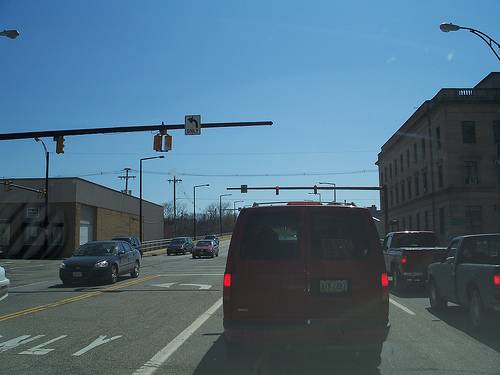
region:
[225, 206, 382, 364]
yellow bus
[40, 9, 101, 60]
white clouds in blue sky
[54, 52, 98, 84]
white clouds in blue sky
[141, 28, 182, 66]
white clouds in blue sky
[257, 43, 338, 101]
white clouds in blue sky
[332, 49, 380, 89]
white clouds in blue sky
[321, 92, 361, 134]
white clouds in blue sky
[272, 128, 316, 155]
white clouds in blue sky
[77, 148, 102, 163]
white clouds in blue sky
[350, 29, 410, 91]
white clouds in blue sky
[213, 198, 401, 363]
Rear of red truck stopping in traffic.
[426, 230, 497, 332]
White pick up truck stopping in traffic.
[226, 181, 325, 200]
Traffic lights hanging over street.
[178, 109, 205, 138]
Directional traffic sign next to traffic lights.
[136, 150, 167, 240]
Lamp post standing on sidewalk.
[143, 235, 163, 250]
Railing along sidwalk next to street.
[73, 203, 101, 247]
Wide white door on side of building.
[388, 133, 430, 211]
Windows along side of building.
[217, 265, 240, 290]
Break light on rear of red truck.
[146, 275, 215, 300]
White traffic directional arrow painted on street.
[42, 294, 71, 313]
a yellow line in the street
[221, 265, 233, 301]
a red light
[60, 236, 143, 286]
a car in the street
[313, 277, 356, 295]
a license plate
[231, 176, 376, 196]
a traffic signal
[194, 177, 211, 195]
a street light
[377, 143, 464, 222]
a building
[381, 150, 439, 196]
windows on the building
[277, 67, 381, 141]
the sky is blue and clear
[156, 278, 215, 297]
a white arrow on the street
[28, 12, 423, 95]
Sky is blue color.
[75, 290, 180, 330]
Road is grey color.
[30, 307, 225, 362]
White lines in road.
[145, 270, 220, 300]
Arrow is white color.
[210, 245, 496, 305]
Red light is on in the car rear.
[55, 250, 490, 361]
Shadow falls on the road.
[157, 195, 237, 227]
Trees are without leaves.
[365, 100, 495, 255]
Building is brown color.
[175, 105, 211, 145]
Board is white and black color.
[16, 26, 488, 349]
Day time picture.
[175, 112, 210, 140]
A square and white sign.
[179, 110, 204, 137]
A white sign with the word ONLY.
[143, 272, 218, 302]
A white arrow pointing left.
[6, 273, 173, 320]
Double yellow line painted on street.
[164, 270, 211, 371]
White line paitned on the street.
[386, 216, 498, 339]
Two pickup trucks on the right.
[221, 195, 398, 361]
Vehicles with brake lights on.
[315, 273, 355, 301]
License tag on back of vehicle.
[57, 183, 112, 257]
White door on building on the left.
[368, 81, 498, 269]
A building on the right.